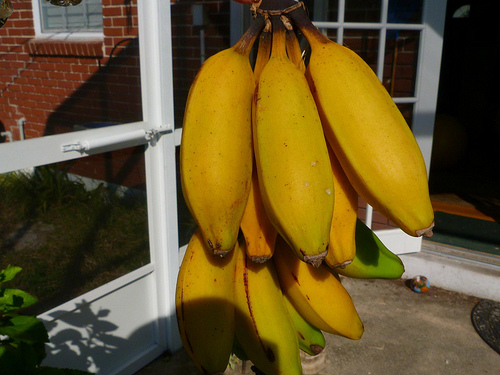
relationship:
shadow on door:
[30, 298, 130, 373] [2, 0, 160, 374]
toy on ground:
[412, 269, 430, 295] [370, 291, 483, 368]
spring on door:
[81, 127, 175, 153] [2, 0, 160, 374]